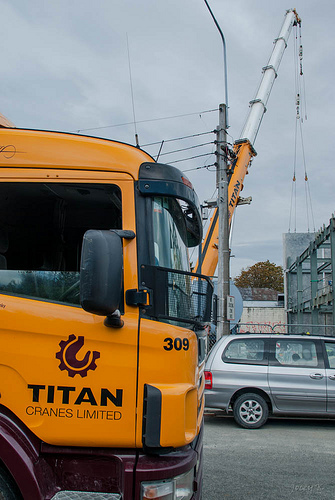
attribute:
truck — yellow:
[0, 127, 212, 499]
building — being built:
[281, 213, 334, 351]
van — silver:
[195, 324, 333, 413]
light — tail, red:
[203, 369, 213, 388]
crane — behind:
[190, 7, 302, 283]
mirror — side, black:
[77, 224, 125, 320]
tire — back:
[231, 393, 267, 431]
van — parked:
[178, 293, 333, 413]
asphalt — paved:
[207, 423, 303, 499]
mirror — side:
[82, 222, 134, 334]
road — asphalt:
[221, 432, 302, 488]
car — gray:
[207, 335, 323, 414]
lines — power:
[154, 106, 214, 172]